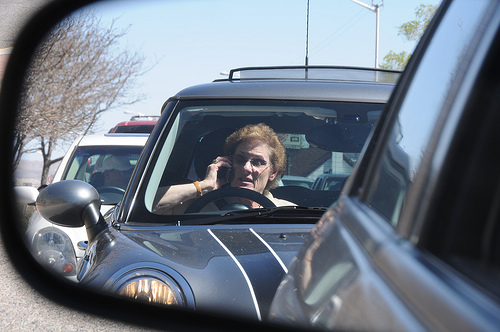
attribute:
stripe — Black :
[207, 226, 298, 325]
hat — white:
[98, 152, 138, 175]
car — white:
[21, 128, 152, 283]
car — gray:
[38, 63, 406, 318]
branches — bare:
[40, 25, 151, 158]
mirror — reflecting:
[53, 9, 418, 329]